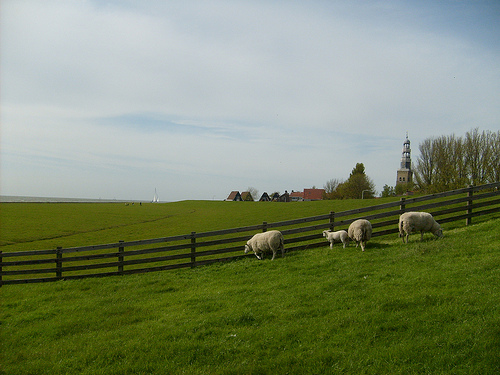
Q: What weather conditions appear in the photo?
A: It is cloudy.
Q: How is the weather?
A: It is cloudy.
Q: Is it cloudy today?
A: Yes, it is cloudy.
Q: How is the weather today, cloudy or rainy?
A: It is cloudy.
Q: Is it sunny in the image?
A: No, it is cloudy.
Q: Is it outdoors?
A: Yes, it is outdoors.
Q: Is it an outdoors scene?
A: Yes, it is outdoors.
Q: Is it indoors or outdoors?
A: It is outdoors.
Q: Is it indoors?
A: No, it is outdoors.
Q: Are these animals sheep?
A: Yes, all the animals are sheep.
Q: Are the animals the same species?
A: Yes, all the animals are sheep.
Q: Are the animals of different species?
A: No, all the animals are sheep.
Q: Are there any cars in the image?
A: No, there are no cars.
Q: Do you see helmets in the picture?
A: No, there are no helmets.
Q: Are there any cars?
A: No, there are no cars.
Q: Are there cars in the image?
A: No, there are no cars.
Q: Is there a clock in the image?
A: No, there are no clocks.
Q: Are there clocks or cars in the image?
A: No, there are no clocks or cars.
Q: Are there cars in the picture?
A: No, there are no cars.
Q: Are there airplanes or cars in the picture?
A: No, there are no cars or airplanes.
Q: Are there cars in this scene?
A: No, there are no cars.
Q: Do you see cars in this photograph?
A: No, there are no cars.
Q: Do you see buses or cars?
A: No, there are no cars or buses.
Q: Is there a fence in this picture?
A: Yes, there is a fence.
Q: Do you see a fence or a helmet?
A: Yes, there is a fence.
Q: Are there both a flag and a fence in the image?
A: No, there is a fence but no flags.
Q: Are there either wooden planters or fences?
A: Yes, there is a wood fence.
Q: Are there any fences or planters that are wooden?
A: Yes, the fence is wooden.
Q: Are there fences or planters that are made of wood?
A: Yes, the fence is made of wood.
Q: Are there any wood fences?
A: Yes, there is a wood fence.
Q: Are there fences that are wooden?
A: Yes, there is a fence that is wooden.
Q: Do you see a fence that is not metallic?
A: Yes, there is a wooden fence.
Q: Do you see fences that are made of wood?
A: Yes, there is a fence that is made of wood.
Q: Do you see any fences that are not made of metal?
A: Yes, there is a fence that is made of wood.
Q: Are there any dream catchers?
A: No, there are no dream catchers.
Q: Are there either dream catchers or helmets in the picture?
A: No, there are no dream catchers or helmets.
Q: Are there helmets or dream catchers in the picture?
A: No, there are no dream catchers or helmets.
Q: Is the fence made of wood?
A: Yes, the fence is made of wood.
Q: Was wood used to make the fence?
A: Yes, the fence is made of wood.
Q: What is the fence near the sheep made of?
A: The fence is made of wood.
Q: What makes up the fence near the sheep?
A: The fence is made of wood.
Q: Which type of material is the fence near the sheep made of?
A: The fence is made of wood.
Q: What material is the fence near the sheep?
A: The fence is made of wood.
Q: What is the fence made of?
A: The fence is made of wood.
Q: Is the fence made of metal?
A: No, the fence is made of wood.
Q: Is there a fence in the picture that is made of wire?
A: No, there is a fence but it is made of wood.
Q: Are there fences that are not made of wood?
A: No, there is a fence but it is made of wood.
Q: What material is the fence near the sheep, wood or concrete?
A: The fence is made of wood.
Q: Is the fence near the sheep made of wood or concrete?
A: The fence is made of wood.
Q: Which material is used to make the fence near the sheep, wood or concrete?
A: The fence is made of wood.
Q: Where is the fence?
A: The fence is on the hill.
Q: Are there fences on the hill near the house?
A: Yes, there is a fence on the hill.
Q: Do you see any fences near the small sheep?
A: Yes, there is a fence near the sheep.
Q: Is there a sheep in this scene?
A: Yes, there is a sheep.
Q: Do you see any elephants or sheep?
A: Yes, there is a sheep.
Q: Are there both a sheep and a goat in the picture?
A: No, there is a sheep but no goats.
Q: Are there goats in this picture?
A: No, there are no goats.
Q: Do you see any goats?
A: No, there are no goats.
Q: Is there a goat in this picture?
A: No, there are no goats.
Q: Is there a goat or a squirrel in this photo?
A: No, there are no goats or squirrels.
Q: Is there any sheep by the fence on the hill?
A: Yes, there is a sheep by the fence.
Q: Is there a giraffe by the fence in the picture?
A: No, there is a sheep by the fence.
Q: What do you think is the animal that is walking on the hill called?
A: The animal is a sheep.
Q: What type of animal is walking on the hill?
A: The animal is a sheep.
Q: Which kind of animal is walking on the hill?
A: The animal is a sheep.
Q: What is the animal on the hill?
A: The animal is a sheep.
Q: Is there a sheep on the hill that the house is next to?
A: Yes, there is a sheep on the hill.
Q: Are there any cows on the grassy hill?
A: No, there is a sheep on the hill.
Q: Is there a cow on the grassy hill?
A: No, there is a sheep on the hill.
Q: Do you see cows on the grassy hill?
A: No, there is a sheep on the hill.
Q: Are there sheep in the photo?
A: Yes, there is a sheep.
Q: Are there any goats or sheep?
A: Yes, there is a sheep.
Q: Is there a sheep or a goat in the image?
A: Yes, there is a sheep.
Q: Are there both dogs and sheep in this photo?
A: No, there is a sheep but no dogs.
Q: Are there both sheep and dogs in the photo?
A: No, there is a sheep but no dogs.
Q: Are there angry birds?
A: No, there are no angry birds.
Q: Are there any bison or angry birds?
A: No, there are no angry birds or bison.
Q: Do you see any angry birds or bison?
A: No, there are no angry birds or bison.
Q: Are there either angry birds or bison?
A: No, there are no angry birds or bison.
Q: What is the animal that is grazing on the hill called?
A: The animal is a sheep.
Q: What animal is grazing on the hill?
A: The animal is a sheep.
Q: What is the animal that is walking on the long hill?
A: The animal is a sheep.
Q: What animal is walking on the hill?
A: The animal is a sheep.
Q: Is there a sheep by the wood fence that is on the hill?
A: Yes, there is a sheep by the fence.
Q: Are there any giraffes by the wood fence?
A: No, there is a sheep by the fence.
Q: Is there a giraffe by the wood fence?
A: No, there is a sheep by the fence.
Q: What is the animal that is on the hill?
A: The animal is a sheep.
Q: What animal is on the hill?
A: The animal is a sheep.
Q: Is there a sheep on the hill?
A: Yes, there is a sheep on the hill.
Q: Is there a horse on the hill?
A: No, there is a sheep on the hill.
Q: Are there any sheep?
A: Yes, there is a sheep.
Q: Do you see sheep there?
A: Yes, there is a sheep.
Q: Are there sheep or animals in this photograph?
A: Yes, there is a sheep.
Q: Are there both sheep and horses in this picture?
A: No, there is a sheep but no horses.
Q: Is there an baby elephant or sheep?
A: Yes, there is a baby sheep.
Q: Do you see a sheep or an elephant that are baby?
A: Yes, the sheep is a baby.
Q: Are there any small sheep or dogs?
A: Yes, there is a small sheep.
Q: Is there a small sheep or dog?
A: Yes, there is a small sheep.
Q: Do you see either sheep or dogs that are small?
A: Yes, the sheep is small.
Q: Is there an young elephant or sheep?
A: Yes, there is a young sheep.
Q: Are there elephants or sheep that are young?
A: Yes, the sheep is young.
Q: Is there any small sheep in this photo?
A: Yes, there is a small sheep.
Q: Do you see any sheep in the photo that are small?
A: Yes, there is a sheep that is small.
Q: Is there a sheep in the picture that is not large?
A: Yes, there is a small sheep.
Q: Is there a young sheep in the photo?
A: Yes, there is a young sheep.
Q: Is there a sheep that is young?
A: Yes, there is a sheep that is young.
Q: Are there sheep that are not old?
A: Yes, there is an young sheep.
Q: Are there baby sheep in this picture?
A: Yes, there is a baby sheep.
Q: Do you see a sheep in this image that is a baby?
A: Yes, there is a sheep that is a baby.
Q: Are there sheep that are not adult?
A: Yes, there is an baby sheep.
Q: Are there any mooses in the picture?
A: No, there are no mooses.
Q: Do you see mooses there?
A: No, there are no mooses.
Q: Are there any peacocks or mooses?
A: No, there are no mooses or peacocks.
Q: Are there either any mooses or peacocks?
A: No, there are no mooses or peacocks.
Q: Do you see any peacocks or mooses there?
A: No, there are no mooses or peacocks.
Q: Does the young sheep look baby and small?
A: Yes, the sheep is a baby and small.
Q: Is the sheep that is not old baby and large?
A: No, the sheep is a baby but small.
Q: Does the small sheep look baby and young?
A: Yes, the sheep is a baby and young.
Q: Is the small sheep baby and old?
A: No, the sheep is a baby but young.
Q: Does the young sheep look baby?
A: Yes, the sheep is a baby.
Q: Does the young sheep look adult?
A: No, the sheep is a baby.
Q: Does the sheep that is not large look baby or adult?
A: The sheep is a baby.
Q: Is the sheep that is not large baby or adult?
A: The sheep is a baby.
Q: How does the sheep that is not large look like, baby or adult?
A: The sheep is a baby.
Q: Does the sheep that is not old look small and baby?
A: Yes, the sheep is small and baby.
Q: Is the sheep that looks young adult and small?
A: No, the sheep is small but baby.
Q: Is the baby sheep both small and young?
A: Yes, the sheep is small and young.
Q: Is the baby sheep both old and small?
A: No, the sheep is small but young.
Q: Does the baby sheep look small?
A: Yes, the sheep is small.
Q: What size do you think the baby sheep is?
A: The sheep is small.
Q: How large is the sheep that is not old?
A: The sheep is small.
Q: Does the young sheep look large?
A: No, the sheep is small.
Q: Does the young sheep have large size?
A: No, the sheep is small.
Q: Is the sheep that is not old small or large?
A: The sheep is small.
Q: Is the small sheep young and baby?
A: Yes, the sheep is young and baby.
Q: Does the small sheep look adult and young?
A: No, the sheep is young but baby.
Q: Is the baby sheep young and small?
A: Yes, the sheep is young and small.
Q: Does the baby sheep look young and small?
A: Yes, the sheep is young and small.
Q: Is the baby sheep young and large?
A: No, the sheep is young but small.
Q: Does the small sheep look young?
A: Yes, the sheep is young.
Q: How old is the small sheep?
A: The sheep is young.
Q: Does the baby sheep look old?
A: No, the sheep is young.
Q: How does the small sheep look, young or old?
A: The sheep is young.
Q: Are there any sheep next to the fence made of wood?
A: Yes, there is a sheep next to the fence.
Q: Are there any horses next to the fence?
A: No, there is a sheep next to the fence.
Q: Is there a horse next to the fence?
A: No, there is a sheep next to the fence.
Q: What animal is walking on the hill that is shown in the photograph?
A: The animal is a sheep.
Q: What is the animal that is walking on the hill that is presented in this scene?
A: The animal is a sheep.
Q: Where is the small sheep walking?
A: The sheep is walking on the hill.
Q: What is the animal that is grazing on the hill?
A: The animal is a sheep.